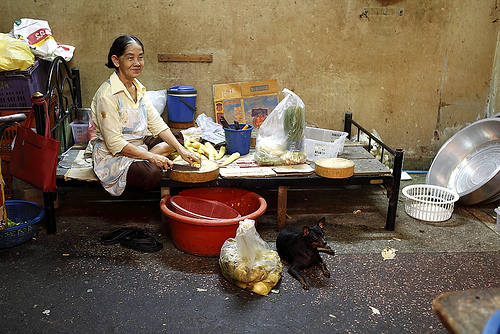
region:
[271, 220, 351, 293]
little black dog on the ground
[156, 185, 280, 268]
bug red wash basins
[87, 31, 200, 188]
Asian woman cutting fruit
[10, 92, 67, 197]
red purse hanging behind person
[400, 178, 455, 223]
empty white basket on ground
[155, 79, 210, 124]
blue portable water jug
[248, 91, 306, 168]
plastic bag of fruit parts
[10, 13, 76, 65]
empty bag on junk pile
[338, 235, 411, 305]
debris on ground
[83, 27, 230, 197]
smiling lady preparing a meal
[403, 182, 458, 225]
white plastic strainer on ground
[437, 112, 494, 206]
large metal bowl on ground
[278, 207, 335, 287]
black dog sitting on ground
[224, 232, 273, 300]
plastic bag on ground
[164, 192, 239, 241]
red plastic bowls on ground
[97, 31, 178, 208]
older lady sitting at table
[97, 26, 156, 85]
lady with darker skin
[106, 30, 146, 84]
lady with black hair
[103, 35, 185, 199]
lady wearing apron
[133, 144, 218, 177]
knife in lady's hand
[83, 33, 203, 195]
a smiling woman sitting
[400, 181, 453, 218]
a slotted white plastic basket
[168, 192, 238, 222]
a red plastic bucket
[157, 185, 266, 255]
a red plastic bucket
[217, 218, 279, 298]
a full clear plastic bag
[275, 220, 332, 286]
a black and brown sitting dog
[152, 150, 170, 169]
the hand of the woman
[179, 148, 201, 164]
the hand of the woman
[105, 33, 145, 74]
the head of the woman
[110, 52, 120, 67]
the ear of the woman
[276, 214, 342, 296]
little furry black dog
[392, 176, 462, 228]
slotted white plastic basket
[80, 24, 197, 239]
happy looking older asian woman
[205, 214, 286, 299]
bag of unidentified yellowy substance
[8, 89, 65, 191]
red hand bag with black zipper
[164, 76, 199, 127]
round blue plastic container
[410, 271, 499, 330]
edge of a worn wooden table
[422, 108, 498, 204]
large silver metal basin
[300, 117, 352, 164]
small transparent plastic crate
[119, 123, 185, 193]
brown pants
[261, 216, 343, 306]
small dog on ground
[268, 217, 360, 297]
brown and black dog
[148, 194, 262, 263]
a large red bowl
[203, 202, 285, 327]
clear sack of banana peel on ground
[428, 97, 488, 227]
silver round bucket tipped sideways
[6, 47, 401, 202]
woman sitting on a bed frame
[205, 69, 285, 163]
a empty quacker oatmeal box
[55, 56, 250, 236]
woman preparing food on bed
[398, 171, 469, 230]
white laundry basket on floor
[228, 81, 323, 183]
a tall clear plastic bag